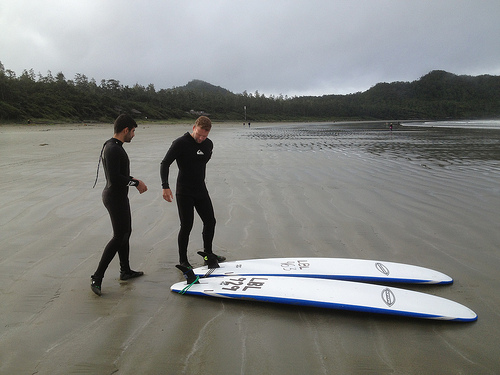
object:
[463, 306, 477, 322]
tip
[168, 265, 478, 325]
surfboard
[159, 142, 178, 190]
arm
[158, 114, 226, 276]
man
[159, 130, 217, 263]
wetsuit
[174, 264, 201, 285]
fin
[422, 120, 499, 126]
wave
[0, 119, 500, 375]
beach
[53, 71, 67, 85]
trees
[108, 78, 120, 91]
trees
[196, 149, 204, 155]
logo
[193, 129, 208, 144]
face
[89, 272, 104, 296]
foot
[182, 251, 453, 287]
surfboard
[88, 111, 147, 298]
man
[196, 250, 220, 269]
fin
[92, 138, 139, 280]
wetsuit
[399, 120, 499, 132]
ocean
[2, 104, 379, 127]
bank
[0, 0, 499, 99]
sky